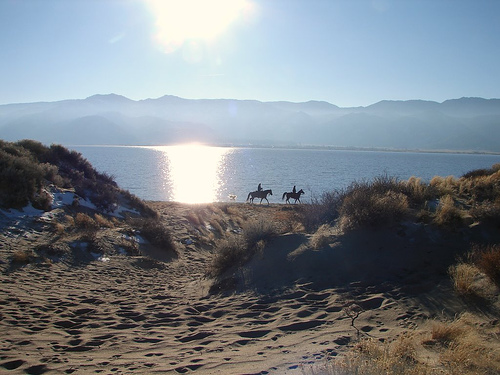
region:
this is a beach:
[30, 40, 398, 308]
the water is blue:
[147, 121, 275, 162]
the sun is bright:
[142, 7, 230, 57]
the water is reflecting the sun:
[135, 131, 265, 229]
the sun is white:
[141, 135, 232, 206]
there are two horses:
[238, 181, 340, 226]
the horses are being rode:
[240, 158, 335, 226]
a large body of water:
[40, 120, 477, 225]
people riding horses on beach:
[223, 168, 310, 222]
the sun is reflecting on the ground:
[141, 140, 243, 209]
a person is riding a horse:
[247, 182, 269, 203]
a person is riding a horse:
[282, 184, 305, 205]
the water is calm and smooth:
[60, 143, 486, 207]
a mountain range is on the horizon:
[2, 85, 489, 152]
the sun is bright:
[135, 0, 262, 63]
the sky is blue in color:
[1, 2, 492, 124]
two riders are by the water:
[245, 180, 309, 205]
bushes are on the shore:
[2, 134, 124, 209]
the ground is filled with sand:
[0, 185, 499, 368]